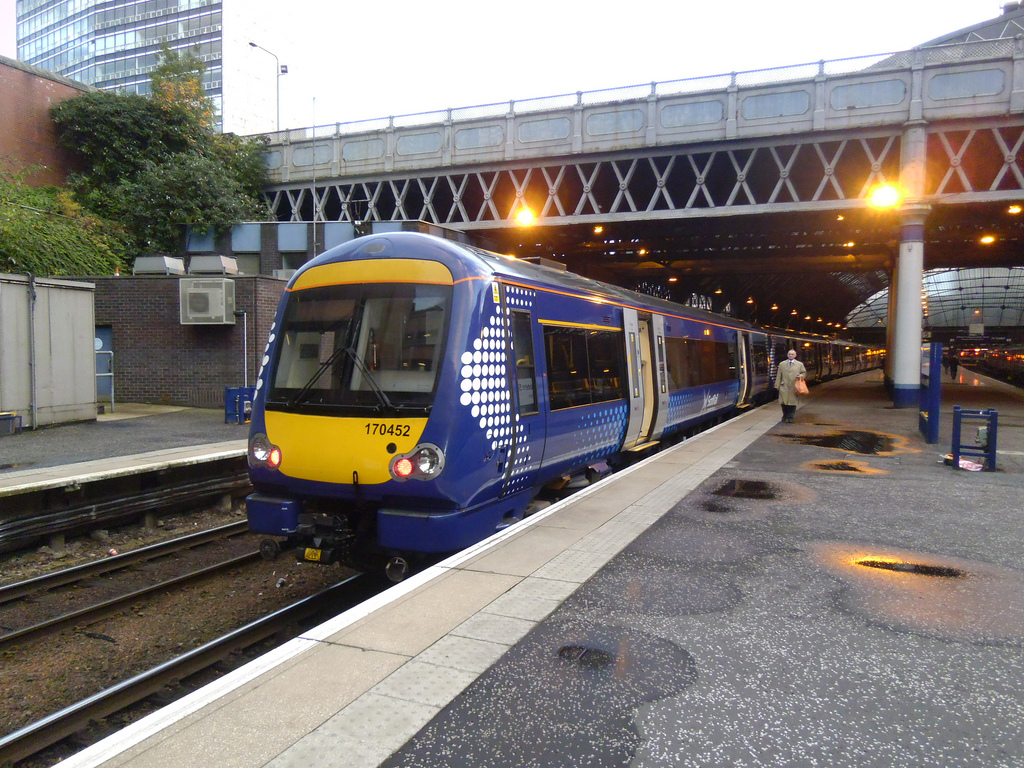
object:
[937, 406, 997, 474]
bars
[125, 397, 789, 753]
sidewalk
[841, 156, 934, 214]
light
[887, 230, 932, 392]
post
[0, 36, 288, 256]
bushes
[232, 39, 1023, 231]
bridge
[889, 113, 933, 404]
post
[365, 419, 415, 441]
numbers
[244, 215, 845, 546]
train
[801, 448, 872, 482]
puddle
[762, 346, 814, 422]
person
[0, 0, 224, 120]
building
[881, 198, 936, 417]
column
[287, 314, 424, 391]
windshield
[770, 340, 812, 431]
man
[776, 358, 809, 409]
coat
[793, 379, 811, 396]
bag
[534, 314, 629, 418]
window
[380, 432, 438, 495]
headlight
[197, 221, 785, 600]
train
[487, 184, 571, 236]
light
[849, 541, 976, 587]
puddles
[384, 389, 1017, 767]
asphalt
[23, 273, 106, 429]
doors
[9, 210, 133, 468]
shed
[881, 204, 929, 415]
column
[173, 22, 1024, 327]
overpass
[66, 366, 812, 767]
concrete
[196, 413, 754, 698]
stripe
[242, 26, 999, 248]
bridge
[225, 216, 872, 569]
train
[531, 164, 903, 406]
tunnel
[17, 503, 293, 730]
tracks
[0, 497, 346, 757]
ground